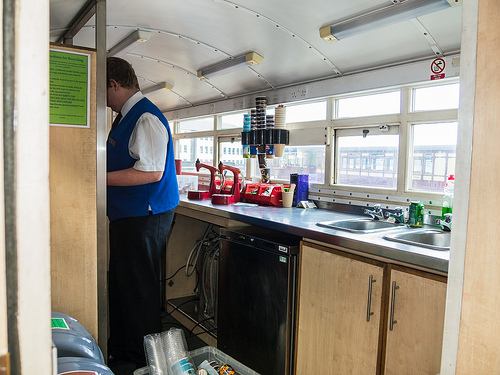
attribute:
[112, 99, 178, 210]
vest — blue 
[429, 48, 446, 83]
white sign — red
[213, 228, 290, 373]
refrigerator — black , Small 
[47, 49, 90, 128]
paper — Green 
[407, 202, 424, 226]
can — Green , aluminium 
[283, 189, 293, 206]
cup — Brown 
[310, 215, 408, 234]
sink — stainless steel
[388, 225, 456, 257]
sink — stainless steel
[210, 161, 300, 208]
containers — red 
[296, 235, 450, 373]
cabinet doors — Brown 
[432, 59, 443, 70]
drawing — black